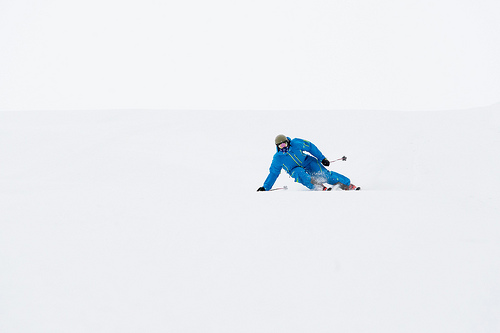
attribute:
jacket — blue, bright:
[259, 136, 354, 191]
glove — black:
[321, 160, 330, 166]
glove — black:
[257, 186, 264, 192]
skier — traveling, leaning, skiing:
[257, 135, 360, 192]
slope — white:
[0, 107, 490, 316]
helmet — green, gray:
[276, 136, 289, 151]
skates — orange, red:
[340, 184, 361, 191]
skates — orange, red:
[315, 184, 333, 193]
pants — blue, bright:
[289, 157, 351, 190]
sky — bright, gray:
[0, 0, 497, 107]